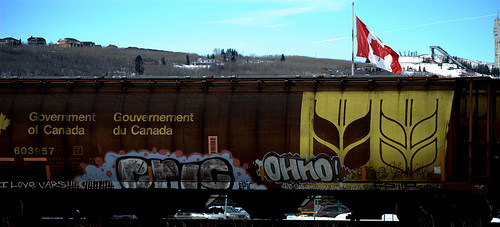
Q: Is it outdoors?
A: Yes, it is outdoors.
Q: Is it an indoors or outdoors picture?
A: It is outdoors.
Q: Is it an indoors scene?
A: No, it is outdoors.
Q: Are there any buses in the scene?
A: No, there are no buses.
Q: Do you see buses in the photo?
A: No, there are no buses.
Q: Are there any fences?
A: No, there are no fences.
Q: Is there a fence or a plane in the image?
A: No, there are no fences or airplanes.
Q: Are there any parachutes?
A: No, there are no parachutes.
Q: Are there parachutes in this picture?
A: No, there are no parachutes.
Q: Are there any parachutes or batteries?
A: No, there are no parachutes or batteries.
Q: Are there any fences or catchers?
A: No, there are no fences or catchers.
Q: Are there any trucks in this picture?
A: No, there are no trucks.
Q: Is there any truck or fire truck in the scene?
A: No, there are no trucks or fire trucks.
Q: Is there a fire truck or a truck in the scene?
A: No, there are no trucks or fire trucks.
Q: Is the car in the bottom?
A: Yes, the car is in the bottom of the image.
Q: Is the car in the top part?
A: No, the car is in the bottom of the image.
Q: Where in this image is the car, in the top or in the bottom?
A: The car is in the bottom of the image.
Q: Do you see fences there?
A: No, there are no fences.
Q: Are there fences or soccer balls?
A: No, there are no fences or soccer balls.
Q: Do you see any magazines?
A: No, there are no magazines.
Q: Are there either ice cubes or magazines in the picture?
A: No, there are no magazines or ice cubes.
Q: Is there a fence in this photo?
A: No, there are no fences.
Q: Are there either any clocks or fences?
A: No, there are no fences or clocks.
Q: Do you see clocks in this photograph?
A: No, there are no clocks.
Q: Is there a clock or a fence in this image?
A: No, there are no clocks or fences.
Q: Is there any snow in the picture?
A: Yes, there is snow.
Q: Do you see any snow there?
A: Yes, there is snow.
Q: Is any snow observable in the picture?
A: Yes, there is snow.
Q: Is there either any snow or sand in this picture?
A: Yes, there is snow.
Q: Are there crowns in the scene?
A: No, there are no crowns.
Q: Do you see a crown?
A: No, there are no crowns.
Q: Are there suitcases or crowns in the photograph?
A: No, there are no crowns or suitcases.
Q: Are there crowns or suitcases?
A: No, there are no crowns or suitcases.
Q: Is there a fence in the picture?
A: No, there are no fences.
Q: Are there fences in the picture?
A: No, there are no fences.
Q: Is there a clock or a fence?
A: No, there are no fences or clocks.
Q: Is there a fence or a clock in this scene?
A: No, there are no fences or clocks.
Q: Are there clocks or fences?
A: No, there are no fences or clocks.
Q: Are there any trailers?
A: No, there are no trailers.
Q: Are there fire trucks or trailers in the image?
A: No, there are no trailers or fire trucks.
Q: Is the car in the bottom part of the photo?
A: Yes, the car is in the bottom of the image.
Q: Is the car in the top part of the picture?
A: No, the car is in the bottom of the image.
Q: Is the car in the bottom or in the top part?
A: The car is in the bottom of the image.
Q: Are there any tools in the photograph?
A: No, there are no tools.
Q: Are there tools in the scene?
A: No, there are no tools.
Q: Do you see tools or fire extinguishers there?
A: No, there are no tools or fire extinguishers.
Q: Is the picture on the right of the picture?
A: Yes, the picture is on the right of the image.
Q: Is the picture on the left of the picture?
A: No, the picture is on the right of the image.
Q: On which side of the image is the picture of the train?
A: The picture is on the right of the image.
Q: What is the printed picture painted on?
A: The picture is painted on the train.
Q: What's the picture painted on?
A: The picture is painted on the train.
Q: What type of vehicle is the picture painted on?
A: The picture is painted on the train.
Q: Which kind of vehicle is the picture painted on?
A: The picture is painted on the train.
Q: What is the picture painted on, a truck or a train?
A: The picture is painted on a train.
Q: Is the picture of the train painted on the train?
A: Yes, the picture is painted on the train.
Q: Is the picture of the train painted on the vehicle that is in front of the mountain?
A: Yes, the picture is painted on the train.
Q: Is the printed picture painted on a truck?
A: No, the picture is painted on the train.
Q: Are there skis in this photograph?
A: No, there are no skis.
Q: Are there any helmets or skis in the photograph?
A: No, there are no skis or helmets.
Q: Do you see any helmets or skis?
A: No, there are no skis or helmets.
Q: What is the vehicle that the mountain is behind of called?
A: The vehicle is a train.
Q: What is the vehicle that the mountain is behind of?
A: The vehicle is a train.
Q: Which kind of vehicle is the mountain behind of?
A: The mountain is behind the train.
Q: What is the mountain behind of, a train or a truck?
A: The mountain is behind a train.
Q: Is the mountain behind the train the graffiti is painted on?
A: Yes, the mountain is behind the train.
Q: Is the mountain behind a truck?
A: No, the mountain is behind the train.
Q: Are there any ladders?
A: No, there are no ladders.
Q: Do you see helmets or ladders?
A: No, there are no ladders or helmets.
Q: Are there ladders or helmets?
A: No, there are no ladders or helmets.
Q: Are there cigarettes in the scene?
A: No, there are no cigarettes.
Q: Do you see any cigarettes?
A: No, there are no cigarettes.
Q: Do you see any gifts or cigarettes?
A: No, there are no cigarettes or gifts.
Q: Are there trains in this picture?
A: Yes, there is a train.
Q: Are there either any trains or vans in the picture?
A: Yes, there is a train.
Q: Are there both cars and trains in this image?
A: Yes, there are both a train and a car.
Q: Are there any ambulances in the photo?
A: No, there are no ambulances.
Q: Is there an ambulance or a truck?
A: No, there are no ambulances or trucks.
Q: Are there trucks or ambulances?
A: No, there are no ambulances or trucks.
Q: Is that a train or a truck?
A: That is a train.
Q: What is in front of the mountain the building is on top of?
A: The train is in front of the mountain.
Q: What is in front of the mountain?
A: The train is in front of the mountain.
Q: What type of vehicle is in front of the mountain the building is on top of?
A: The vehicle is a train.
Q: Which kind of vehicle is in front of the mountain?
A: The vehicle is a train.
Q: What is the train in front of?
A: The train is in front of the mountain.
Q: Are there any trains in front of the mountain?
A: Yes, there is a train in front of the mountain.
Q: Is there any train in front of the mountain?
A: Yes, there is a train in front of the mountain.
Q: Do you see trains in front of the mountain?
A: Yes, there is a train in front of the mountain.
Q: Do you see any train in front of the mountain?
A: Yes, there is a train in front of the mountain.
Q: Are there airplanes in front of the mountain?
A: No, there is a train in front of the mountain.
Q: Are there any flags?
A: Yes, there is a flag.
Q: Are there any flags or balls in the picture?
A: Yes, there is a flag.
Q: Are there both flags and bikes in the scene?
A: No, there is a flag but no bikes.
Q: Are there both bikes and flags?
A: No, there is a flag but no bikes.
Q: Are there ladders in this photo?
A: No, there are no ladders.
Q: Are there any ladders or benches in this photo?
A: No, there are no ladders or benches.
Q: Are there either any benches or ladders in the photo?
A: No, there are no ladders or benches.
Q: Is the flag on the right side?
A: Yes, the flag is on the right of the image.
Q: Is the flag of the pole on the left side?
A: No, the flag is on the right of the image.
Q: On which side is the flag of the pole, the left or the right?
A: The flag is on the right of the image.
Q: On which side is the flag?
A: The flag is on the right of the image.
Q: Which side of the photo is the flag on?
A: The flag is on the right of the image.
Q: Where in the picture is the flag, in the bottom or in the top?
A: The flag is in the top of the image.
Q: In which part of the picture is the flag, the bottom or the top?
A: The flag is in the top of the image.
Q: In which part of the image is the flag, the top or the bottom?
A: The flag is in the top of the image.